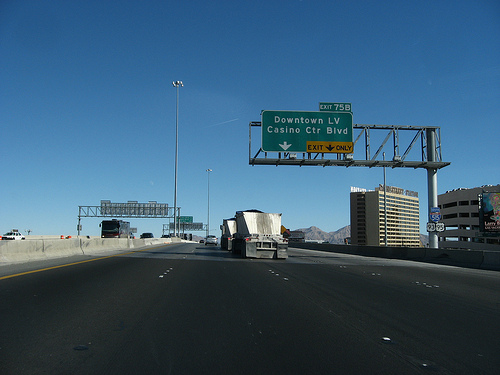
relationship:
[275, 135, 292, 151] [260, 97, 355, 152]
arrow on sign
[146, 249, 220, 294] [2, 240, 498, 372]
lines on road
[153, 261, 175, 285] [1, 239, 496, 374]
lines painted on highway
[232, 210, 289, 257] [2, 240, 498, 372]
truck on road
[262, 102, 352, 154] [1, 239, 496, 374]
sign over an highway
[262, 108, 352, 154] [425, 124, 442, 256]
sign on pole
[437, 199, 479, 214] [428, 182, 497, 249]
windows on building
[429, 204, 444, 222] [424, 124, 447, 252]
sign on pole